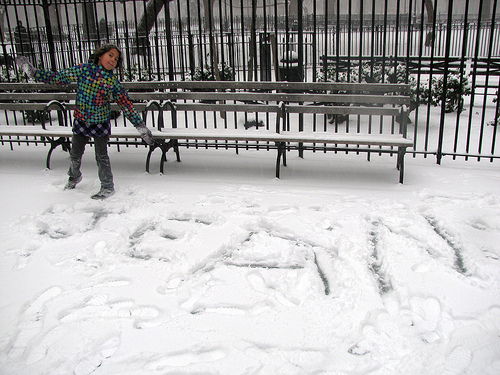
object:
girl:
[17, 44, 151, 198]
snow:
[1, 18, 496, 371]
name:
[34, 195, 497, 294]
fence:
[0, 0, 499, 162]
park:
[4, 1, 498, 372]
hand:
[136, 122, 155, 148]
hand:
[12, 57, 37, 74]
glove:
[138, 125, 155, 146]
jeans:
[67, 130, 117, 194]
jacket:
[34, 63, 150, 127]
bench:
[3, 81, 413, 182]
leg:
[395, 151, 408, 180]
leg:
[274, 142, 289, 177]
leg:
[158, 133, 182, 173]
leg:
[146, 141, 159, 173]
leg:
[43, 138, 59, 170]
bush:
[186, 64, 232, 105]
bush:
[430, 73, 467, 115]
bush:
[365, 60, 386, 87]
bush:
[323, 74, 355, 123]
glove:
[18, 53, 35, 79]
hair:
[88, 45, 123, 75]